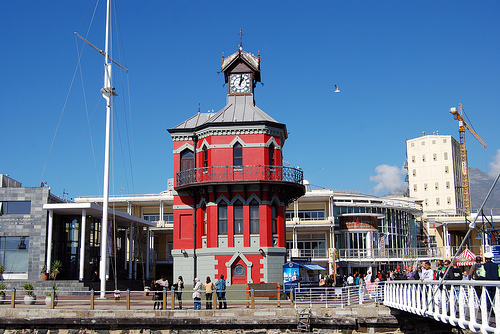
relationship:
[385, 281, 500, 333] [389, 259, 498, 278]
fence near people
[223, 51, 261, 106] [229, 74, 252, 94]
roof has a clock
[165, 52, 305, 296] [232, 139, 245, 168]
building has windows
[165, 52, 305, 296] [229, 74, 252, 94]
building has a clock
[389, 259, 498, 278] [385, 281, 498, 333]
people are near a fence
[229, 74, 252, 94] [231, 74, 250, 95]
clock has numbers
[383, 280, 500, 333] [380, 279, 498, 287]
bridge has a railing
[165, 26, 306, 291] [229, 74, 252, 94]
building has a clock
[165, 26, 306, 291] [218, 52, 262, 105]
building has a top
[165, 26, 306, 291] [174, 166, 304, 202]
building has a balcony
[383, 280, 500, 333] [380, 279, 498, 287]
bridge has railing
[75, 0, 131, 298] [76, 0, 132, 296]
pole from a sail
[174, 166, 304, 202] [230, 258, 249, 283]
balcony has a door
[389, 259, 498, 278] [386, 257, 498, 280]
people are in a crowd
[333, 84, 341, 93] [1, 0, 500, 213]
bird in air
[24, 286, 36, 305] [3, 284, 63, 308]
plants are in a line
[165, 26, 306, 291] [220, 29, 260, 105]
building has a steeple